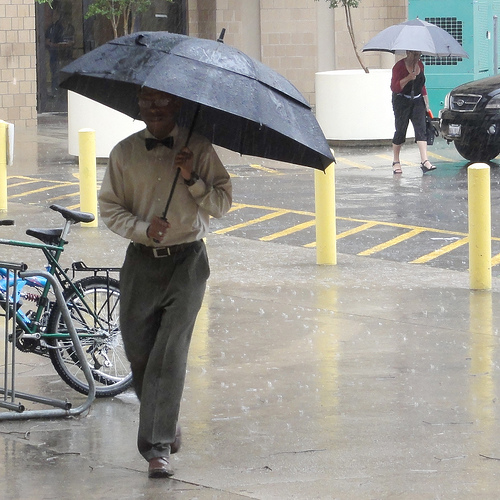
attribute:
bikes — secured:
[1, 234, 83, 367]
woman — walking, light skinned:
[377, 57, 435, 169]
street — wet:
[263, 223, 327, 272]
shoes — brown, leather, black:
[129, 436, 180, 468]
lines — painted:
[229, 200, 302, 243]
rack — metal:
[5, 378, 52, 412]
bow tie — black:
[134, 135, 170, 152]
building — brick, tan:
[4, 65, 33, 102]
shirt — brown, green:
[104, 168, 166, 194]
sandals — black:
[416, 157, 433, 171]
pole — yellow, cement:
[58, 125, 95, 193]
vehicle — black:
[434, 78, 496, 152]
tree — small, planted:
[100, 8, 125, 34]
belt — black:
[129, 242, 184, 260]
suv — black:
[435, 92, 473, 147]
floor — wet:
[236, 249, 275, 293]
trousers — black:
[131, 286, 193, 307]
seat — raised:
[53, 201, 89, 222]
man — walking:
[51, 23, 248, 483]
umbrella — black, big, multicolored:
[68, 12, 337, 194]